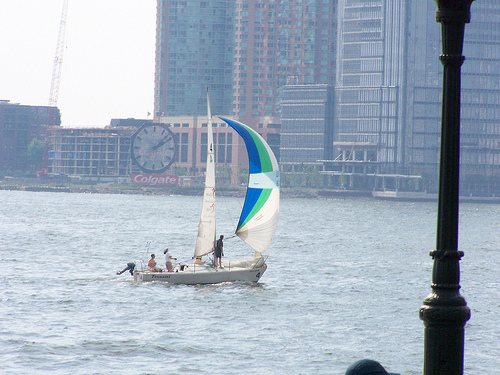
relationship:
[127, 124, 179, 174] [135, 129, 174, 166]
clock has face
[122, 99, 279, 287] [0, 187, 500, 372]
sailboat in water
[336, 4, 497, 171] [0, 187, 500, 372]
skyscraper by water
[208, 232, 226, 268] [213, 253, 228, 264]
man wearing shorts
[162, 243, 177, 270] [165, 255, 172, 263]
woman wearing shirt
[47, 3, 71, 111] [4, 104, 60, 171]
crane over building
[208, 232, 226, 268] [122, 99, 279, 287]
man on sailboat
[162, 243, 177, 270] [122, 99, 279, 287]
woman on sailboat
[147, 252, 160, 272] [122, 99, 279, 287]
person on sailboat